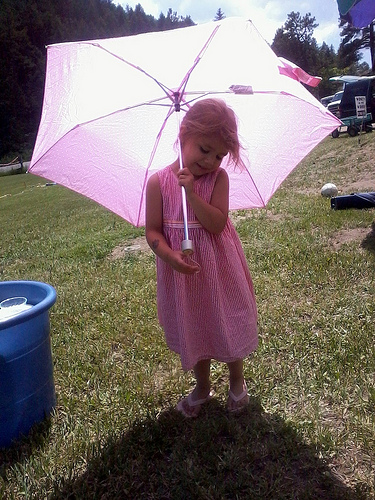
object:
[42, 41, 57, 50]
umbrella end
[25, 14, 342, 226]
umbrella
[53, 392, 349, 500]
shadow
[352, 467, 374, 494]
grass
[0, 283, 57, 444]
tub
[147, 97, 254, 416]
girl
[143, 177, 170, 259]
arm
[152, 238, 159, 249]
fake tattoo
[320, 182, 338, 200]
soccer ball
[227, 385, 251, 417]
left flip flop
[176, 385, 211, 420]
right flip flop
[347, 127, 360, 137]
wheel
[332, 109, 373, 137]
wagon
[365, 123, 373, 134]
wheel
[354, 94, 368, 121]
sign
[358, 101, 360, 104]
letters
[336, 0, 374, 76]
tree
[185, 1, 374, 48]
sky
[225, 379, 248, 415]
foot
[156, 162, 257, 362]
sun dress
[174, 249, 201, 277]
hand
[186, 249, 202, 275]
loop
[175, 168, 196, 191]
hand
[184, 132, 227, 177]
face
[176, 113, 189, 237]
pole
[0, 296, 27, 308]
cup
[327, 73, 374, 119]
van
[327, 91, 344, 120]
car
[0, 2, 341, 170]
wall of trees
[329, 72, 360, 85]
back door